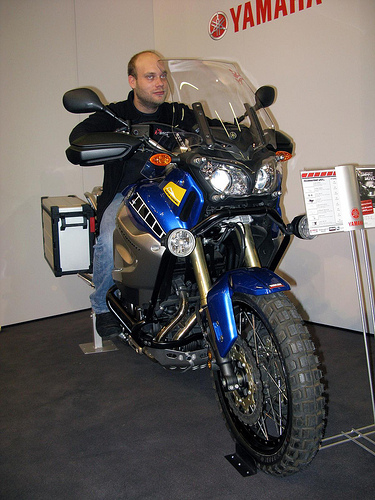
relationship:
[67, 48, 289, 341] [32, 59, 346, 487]
man sitting on bike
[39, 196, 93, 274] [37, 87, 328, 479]
box on side of bike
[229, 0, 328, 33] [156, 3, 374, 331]
letters on wall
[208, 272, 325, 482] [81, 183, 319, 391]
tire of motorcycle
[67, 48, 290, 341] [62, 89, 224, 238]
man wears jacket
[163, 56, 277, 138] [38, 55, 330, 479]
window of motorcycle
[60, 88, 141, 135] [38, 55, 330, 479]
mirror on side of motorcycle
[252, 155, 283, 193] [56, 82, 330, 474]
headlight of motorcycle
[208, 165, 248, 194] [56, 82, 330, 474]
front lights of motorcycle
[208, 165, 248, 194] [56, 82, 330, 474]
front lights on motorcycle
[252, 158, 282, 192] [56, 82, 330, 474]
headlight on motorcycle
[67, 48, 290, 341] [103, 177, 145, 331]
man wearing jeans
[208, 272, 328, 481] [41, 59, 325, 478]
tire on bike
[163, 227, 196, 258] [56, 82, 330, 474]
light on motorcycle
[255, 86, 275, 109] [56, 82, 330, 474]
mirror on motorcycle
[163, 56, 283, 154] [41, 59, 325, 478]
window on bike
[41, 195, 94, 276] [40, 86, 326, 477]
box on motor cycle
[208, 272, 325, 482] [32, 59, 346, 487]
tire of bike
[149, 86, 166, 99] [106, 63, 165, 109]
mouth of man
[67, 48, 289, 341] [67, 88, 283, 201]
man wears jacket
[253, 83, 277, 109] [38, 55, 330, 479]
mirror on side of motorcycle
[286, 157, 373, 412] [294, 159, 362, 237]
stand displays catalog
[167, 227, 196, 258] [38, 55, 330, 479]
light on motorcycle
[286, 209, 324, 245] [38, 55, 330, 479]
light on motorcycle